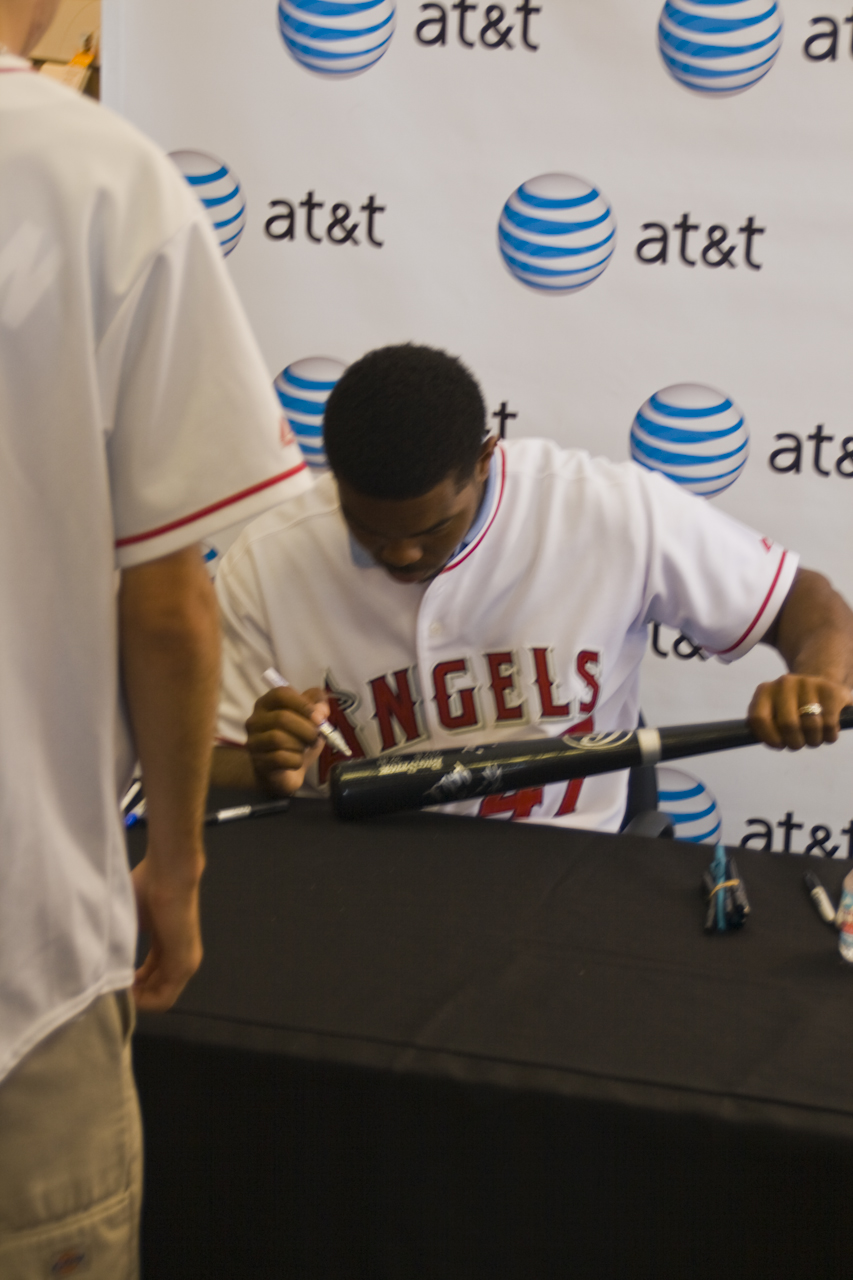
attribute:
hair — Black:
[322, 336, 493, 509]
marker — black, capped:
[206, 793, 302, 829]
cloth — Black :
[107, 778, 850, 1277]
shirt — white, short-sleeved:
[2, 42, 316, 1158]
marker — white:
[259, 665, 357, 761]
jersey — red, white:
[204, 440, 803, 836]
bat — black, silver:
[325, 691, 851, 831]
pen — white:
[264, 664, 356, 760]